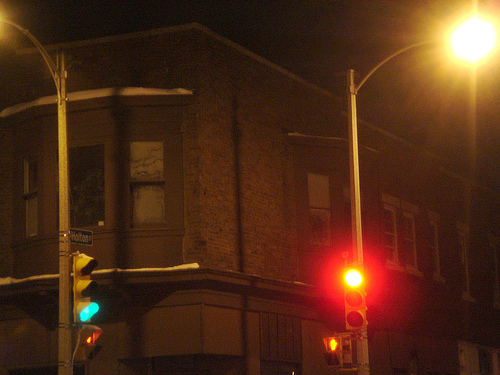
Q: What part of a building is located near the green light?
A: A window with two sections.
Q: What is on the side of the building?
A: Brown bricks.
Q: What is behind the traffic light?
A: A brown brick building.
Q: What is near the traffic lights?
A: A brick building.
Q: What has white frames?
A: Windows.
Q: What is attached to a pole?
A: A traffic signal.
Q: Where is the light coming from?
A: A street light on a pole.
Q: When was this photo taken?
A: At night.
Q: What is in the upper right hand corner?
A: Street light.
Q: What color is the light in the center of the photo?
A: Red.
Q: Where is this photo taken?
A: At an intersection.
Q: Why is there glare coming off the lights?
A: Because it is night time.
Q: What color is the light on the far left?
A: Green.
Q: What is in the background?
A: A building.